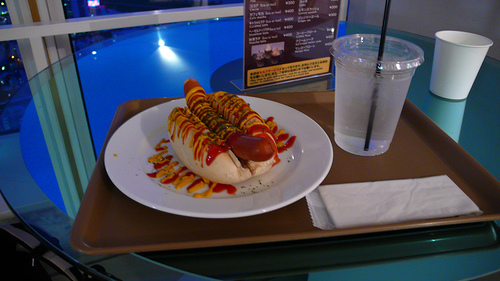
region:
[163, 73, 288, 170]
food item on plate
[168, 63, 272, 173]
toppings on food item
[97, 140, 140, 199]
white plate in photo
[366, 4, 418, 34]
straw in the drink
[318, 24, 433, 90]
top part of cup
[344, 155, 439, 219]
napkin net to cup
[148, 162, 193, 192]
sauce next to hot dog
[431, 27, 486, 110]
cup next to the tray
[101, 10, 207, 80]
window next to the hot dog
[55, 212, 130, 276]
corner of the tray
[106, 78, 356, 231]
a hot dog on a plate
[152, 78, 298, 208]
the hot dog has mustard and ketchup drizzle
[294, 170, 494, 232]
napkins on a tray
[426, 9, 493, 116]
a white paper cup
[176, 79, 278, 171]
this hot dog is long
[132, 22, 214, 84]
a light reflection on a table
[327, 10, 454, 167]
a cup of water on a tray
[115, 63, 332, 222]
a white plate with a hot dog on it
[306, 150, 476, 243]
a napkin on a tray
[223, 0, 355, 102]
a menu near a tray of food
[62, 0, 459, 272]
a tray sitting on a glass table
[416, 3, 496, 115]
a white cup on a table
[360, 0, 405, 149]
a black straw in a cup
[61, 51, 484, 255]
a brown tray with food on it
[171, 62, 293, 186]
a hot dog sitting in a hot dog bunn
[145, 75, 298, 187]
a hot dogn on a white plate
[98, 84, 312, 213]
a round white plate with a hot dog on top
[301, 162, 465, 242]
a white napkin on a tray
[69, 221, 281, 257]
a brown plastic tray on a table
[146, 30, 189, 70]
light being reflected on the glass table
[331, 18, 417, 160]
a clear plastic cup filled with water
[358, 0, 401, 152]
a plastic black straw in a cup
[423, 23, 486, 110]
a white paper cup on a glass table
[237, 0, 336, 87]
a menu on a glass table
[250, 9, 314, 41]
white lettering on a brown menu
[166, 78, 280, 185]
hot dog with ketchup and bright yellow mustard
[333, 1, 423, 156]
beverage in clear plastic cup with straw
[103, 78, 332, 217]
hotdog in bun served on round white plate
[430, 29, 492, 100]
paper cup for hot beverages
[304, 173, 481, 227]
rectangular paper napkin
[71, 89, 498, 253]
rectangular brown food serving tray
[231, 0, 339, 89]
menu in vertical plastic holder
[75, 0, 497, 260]
fast food meal on serving tray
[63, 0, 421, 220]
hot dog and beverage meal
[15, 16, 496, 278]
round glass tabletop